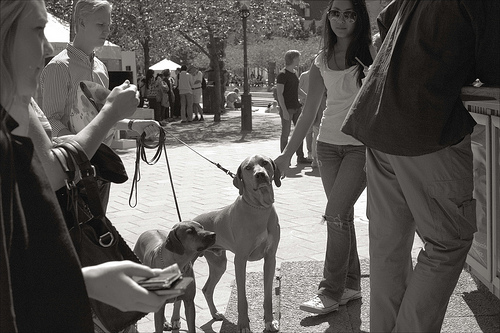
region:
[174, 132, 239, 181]
a leash on dog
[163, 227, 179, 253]
an ear on the dog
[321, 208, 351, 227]
a tear in woman's jeans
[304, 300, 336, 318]
athletic shoe on woman's foot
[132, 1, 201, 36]
leaves in the tree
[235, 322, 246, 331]
a paw on dog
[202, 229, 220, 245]
the nose on dog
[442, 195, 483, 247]
a pocket on person's pants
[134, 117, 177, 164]
man's hand holding leash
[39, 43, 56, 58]
nose on the lady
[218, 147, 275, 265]
A dog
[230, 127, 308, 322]
A dog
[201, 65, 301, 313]
A dog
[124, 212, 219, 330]
small dog on a leash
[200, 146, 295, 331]
big dog on a leash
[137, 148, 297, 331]
two dogs standing on the street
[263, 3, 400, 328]
woman in a white shirt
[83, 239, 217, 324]
hand holding objects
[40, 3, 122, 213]
man looking at the dogs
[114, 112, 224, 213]
two dog leashes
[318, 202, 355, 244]
holes in a pair of jeans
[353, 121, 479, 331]
a pair of men's pants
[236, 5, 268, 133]
a black light post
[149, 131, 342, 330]
to dogs on leashes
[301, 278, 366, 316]
white shoes being covered in jens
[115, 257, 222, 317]
something be held in the hand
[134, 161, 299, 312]
two friends for a lifetime dogs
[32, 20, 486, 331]
people milling about comparing good deed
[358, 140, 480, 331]
wrinkly khahi pants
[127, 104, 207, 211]
leashes being held by a human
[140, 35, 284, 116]
people buying refreshmint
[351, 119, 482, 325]
man wearing khakis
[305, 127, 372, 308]
jeans with a hole in the knee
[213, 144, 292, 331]
the dog is tall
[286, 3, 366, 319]
the woman is wearing sunglasses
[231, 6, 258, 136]
the lamp is off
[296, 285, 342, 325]
the shoe is white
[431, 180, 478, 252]
the pants have a pocket on the side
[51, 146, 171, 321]
the purse is big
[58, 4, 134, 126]
the man is standing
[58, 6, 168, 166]
the man is holding the leash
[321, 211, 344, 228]
the jeans have a hole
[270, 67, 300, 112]
the shirt is black